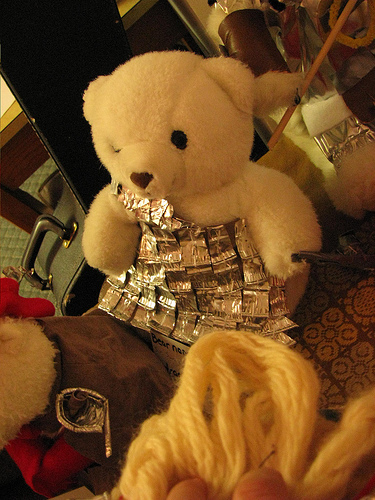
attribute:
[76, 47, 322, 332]
bear — white, teddy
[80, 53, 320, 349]
teddy bear — white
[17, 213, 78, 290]
handle — black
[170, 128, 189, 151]
eye — black 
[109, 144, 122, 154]
eye — black 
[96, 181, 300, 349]
foil — silver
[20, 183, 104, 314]
briefcase — black 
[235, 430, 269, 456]
cream — cream colored, woolen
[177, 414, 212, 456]
strings — thick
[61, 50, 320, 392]
teddy bear — white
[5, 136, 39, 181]
table — brown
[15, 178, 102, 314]
box — dark green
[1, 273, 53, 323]
doll — red 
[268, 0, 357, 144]
stick — Thin, long, brown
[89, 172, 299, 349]
clothing — silvery 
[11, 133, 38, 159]
table — wooden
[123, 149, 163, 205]
nose — brown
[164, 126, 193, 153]
eyes — black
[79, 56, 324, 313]
bear — fluffy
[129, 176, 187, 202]
smile — teddy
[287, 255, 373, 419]
ground — brown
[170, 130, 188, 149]
eye — button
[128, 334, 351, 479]
wool — lime white 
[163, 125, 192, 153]
eye — dark, black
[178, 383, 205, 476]
string — wool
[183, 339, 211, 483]
string — wool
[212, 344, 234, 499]
string — wool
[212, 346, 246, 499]
string — wool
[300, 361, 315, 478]
string — wool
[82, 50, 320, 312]
teddy bear — white